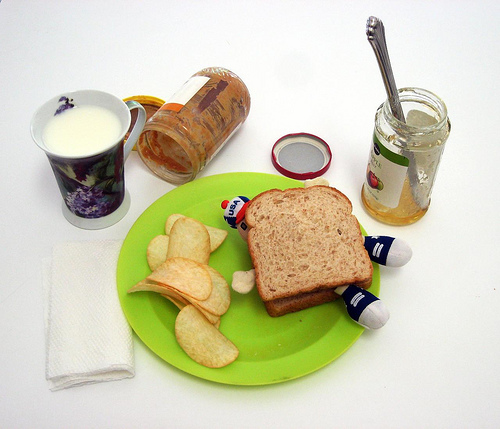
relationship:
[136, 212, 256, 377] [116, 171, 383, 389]
chips on plate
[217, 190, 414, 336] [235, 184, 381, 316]
doll between bread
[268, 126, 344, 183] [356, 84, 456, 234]
lid besides jar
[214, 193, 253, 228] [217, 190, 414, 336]
hat on doll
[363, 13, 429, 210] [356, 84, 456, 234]
knife in jar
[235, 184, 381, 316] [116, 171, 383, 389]
bread on plate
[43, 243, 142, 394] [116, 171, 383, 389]
napkin next to plate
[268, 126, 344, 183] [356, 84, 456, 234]
lid near jar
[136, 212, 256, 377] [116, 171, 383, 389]
chips are on plate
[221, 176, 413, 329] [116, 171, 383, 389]
doll on plate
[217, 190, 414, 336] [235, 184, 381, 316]
doll in bread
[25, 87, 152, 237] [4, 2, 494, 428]
mug on table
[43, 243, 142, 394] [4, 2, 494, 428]
napkin on table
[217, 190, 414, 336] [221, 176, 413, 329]
doll in doll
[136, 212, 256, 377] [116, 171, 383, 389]
chips atop plate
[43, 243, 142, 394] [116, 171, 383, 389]
napkin beside plate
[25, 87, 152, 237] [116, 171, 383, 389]
mug near plate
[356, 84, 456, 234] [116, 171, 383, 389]
jar next to plate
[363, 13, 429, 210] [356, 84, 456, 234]
knife inside jar